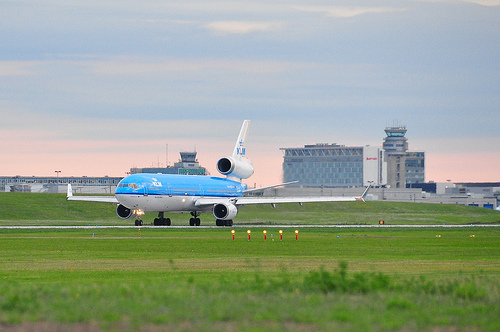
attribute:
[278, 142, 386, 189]
building — large, distant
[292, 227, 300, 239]
light — warning, red, small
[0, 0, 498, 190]
sky — blue, pink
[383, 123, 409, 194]
tower — air control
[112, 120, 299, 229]
plane — blue and white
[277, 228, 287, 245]
light — small, red, warning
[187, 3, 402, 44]
clouds — small, white, wispy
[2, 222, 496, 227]
runway — paved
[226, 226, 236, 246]
light — small, red, warning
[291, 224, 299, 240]
post — red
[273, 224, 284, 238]
post — red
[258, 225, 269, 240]
post — red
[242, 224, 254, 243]
post — red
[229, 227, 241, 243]
post — red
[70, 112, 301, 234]
airplane — blue, white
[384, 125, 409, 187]
tower — tall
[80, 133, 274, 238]
airplane — blue and white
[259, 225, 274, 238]
warning light — red, small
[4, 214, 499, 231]
runway — gray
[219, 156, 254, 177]
engine — large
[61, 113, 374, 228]
plane — blue and white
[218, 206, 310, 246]
light — warning, red, small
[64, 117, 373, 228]
airplane — blue, white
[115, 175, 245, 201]
top half — blue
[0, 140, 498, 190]
lower section — pink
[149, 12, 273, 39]
cloud — white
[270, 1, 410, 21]
cloud — white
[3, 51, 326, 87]
cloud — white